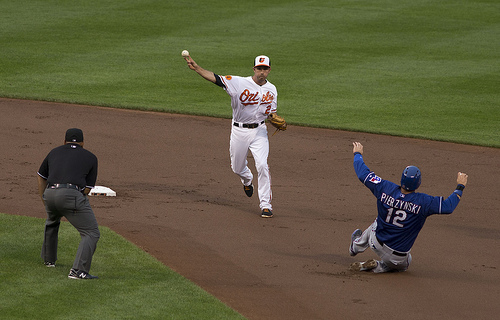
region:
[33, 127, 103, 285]
umpire at baseball game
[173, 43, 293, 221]
baseball player throwing ball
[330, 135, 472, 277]
baseball player siding into base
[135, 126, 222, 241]
brown dirt on baseball field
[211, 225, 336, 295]
brown dirt on baseball field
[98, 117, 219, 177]
brown dirt on baseball field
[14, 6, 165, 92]
green grass on baseball field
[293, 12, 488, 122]
green grass on baseball field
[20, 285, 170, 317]
green grass on baseball field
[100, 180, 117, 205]
white base on baseball field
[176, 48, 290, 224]
A man throws the ball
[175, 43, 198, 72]
The ball leaving his hand.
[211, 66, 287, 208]
The man wears a white uniform.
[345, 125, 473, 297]
The player slides.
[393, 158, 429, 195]
The man has a blue helmet.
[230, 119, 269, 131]
The black belt.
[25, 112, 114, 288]
The umpire hunched over.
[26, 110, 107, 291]
Man stands in the grass.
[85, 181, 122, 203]
The white second base.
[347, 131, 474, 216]
Mans arms in the air.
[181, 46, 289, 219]
Man is an Orioles player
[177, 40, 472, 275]
Two baseball players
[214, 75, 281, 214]
Baseball uniform is white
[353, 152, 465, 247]
Baseball uniform is blue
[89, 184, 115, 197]
The base is white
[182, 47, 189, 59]
Baseball is white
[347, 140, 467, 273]
Baseball player is sliding on dirt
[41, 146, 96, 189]
Man's shirt is black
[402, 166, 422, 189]
Man's helmet is blue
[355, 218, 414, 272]
Player's pants are gray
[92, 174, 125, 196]
a baseball plate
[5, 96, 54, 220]
footprints in the dirt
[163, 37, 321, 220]
a baseball player throwing a ball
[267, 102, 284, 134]
a brown baseball glove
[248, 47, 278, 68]
orange and white baseball cap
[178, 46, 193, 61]
a baseball in the air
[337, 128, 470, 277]
a baseball player sliding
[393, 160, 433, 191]
a blue baseball helmet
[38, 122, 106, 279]
an umpire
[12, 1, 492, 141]
the grassy outfield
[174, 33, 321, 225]
A baseball player throwing a ball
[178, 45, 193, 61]
A baseball being thrown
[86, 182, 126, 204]
a baseball plate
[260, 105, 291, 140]
A brown baseball glove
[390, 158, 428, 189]
A blue batter's helmet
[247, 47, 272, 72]
A white and orange baseball cap